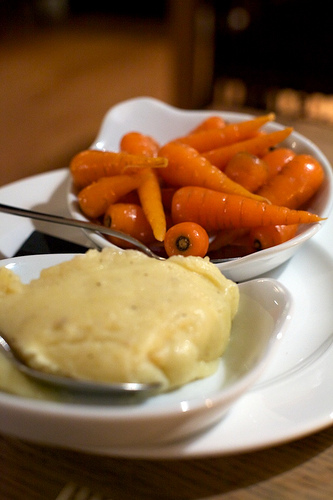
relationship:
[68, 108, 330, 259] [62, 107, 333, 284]
carrots in dish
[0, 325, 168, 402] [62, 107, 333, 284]
spoon in dish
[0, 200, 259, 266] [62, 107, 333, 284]
spoon in dish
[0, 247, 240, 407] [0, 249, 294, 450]
food in dish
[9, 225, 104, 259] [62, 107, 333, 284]
napkin under dish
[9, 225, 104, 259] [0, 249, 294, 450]
napkin under dish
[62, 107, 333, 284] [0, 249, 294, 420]
dish on top of dish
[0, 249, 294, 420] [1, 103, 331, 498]
dish on table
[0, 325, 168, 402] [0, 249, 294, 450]
spoon in dish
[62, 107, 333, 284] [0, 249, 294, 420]
dish on dish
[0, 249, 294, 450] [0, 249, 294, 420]
dish on dish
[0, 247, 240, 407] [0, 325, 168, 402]
food on spoon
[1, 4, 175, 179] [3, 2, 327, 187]
floor in background